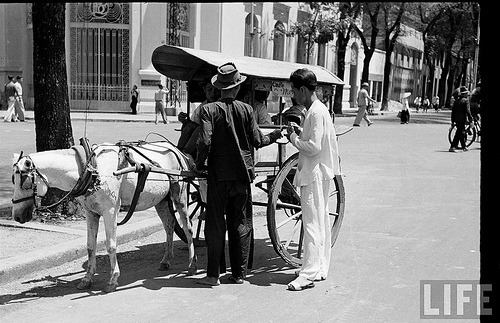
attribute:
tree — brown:
[32, 0, 84, 217]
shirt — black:
[183, 87, 270, 196]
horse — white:
[3, 130, 212, 299]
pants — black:
[205, 159, 256, 303]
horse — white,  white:
[12, 139, 209, 292]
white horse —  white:
[9, 137, 203, 292]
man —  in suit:
[280, 69, 340, 293]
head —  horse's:
[10, 144, 55, 252]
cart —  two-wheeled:
[147, 42, 345, 271]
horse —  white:
[0, 112, 192, 266]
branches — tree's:
[353, 7, 378, 52]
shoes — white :
[281, 267, 321, 296]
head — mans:
[204, 64, 246, 103]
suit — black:
[197, 102, 262, 269]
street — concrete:
[1, 108, 481, 321]